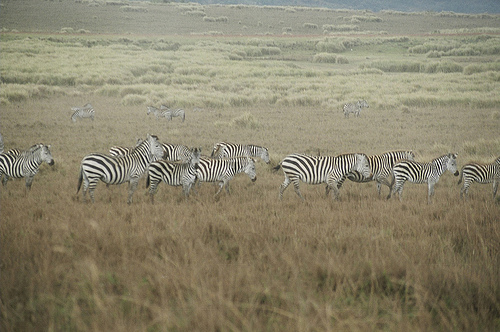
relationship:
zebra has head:
[269, 151, 374, 199] [355, 150, 374, 180]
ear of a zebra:
[146, 133, 158, 145] [76, 133, 169, 192]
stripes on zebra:
[283, 152, 360, 182] [460, 154, 499, 193]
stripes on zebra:
[283, 152, 360, 182] [272, 150, 375, 204]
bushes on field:
[0, 0, 497, 112] [6, 6, 481, 327]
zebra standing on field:
[339, 100, 365, 120] [6, 6, 481, 327]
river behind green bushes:
[227, 9, 497, 45] [0, 0, 497, 112]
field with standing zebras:
[6, 6, 481, 327] [95, 138, 437, 210]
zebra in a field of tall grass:
[269, 151, 374, 199] [186, 215, 452, 307]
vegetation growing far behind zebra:
[3, 2, 499, 130] [269, 151, 374, 199]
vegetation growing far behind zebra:
[3, 2, 499, 130] [73, 133, 169, 201]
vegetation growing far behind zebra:
[3, 2, 499, 130] [388, 150, 459, 206]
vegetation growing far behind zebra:
[3, 2, 499, 130] [457, 152, 499, 196]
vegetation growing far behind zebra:
[3, 2, 499, 130] [143, 144, 203, 203]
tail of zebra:
[73, 171, 85, 197] [71, 129, 169, 205]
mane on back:
[126, 133, 153, 152] [72, 143, 156, 168]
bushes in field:
[8, 0, 468, 112] [6, 6, 481, 327]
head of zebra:
[37, 143, 54, 165] [1, 145, 54, 191]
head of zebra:
[143, 132, 168, 161] [73, 133, 169, 201]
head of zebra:
[187, 147, 202, 170] [110, 135, 160, 166]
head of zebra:
[241, 155, 257, 180] [145, 149, 202, 205]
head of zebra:
[260, 145, 272, 162] [152, 139, 192, 164]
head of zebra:
[352, 153, 374, 178] [197, 154, 257, 197]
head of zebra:
[406, 148, 416, 162] [210, 138, 271, 167]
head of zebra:
[441, 152, 460, 174] [269, 151, 374, 199]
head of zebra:
[359, 100, 369, 108] [342, 148, 415, 194]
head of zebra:
[355, 100, 361, 108] [388, 150, 459, 206]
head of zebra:
[156, 102, 163, 108] [455, 153, 498, 193]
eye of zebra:
[362, 159, 377, 177] [278, 148, 384, 191]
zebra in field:
[269, 151, 374, 199] [6, 6, 481, 327]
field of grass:
[6, 6, 481, 327] [283, 226, 422, 308]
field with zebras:
[6, 6, 481, 327] [43, 76, 489, 276]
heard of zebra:
[0, 95, 499, 205] [269, 151, 374, 199]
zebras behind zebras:
[63, 102, 194, 125] [0, 133, 499, 203]